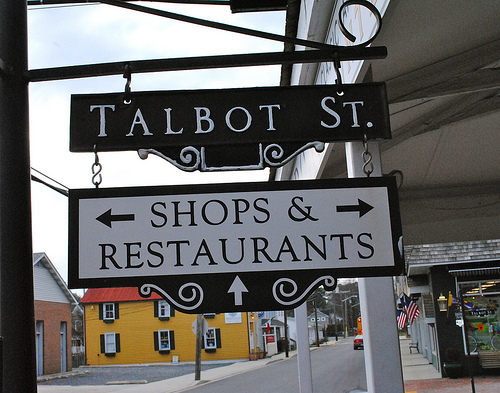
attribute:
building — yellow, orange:
[71, 285, 257, 377]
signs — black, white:
[82, 102, 395, 277]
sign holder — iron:
[330, 136, 407, 387]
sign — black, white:
[71, 190, 408, 290]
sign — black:
[63, 62, 389, 170]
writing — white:
[94, 110, 364, 133]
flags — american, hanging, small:
[396, 296, 428, 334]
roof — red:
[79, 284, 150, 301]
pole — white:
[316, 79, 412, 385]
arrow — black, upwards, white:
[77, 202, 148, 230]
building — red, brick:
[22, 304, 89, 379]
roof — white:
[36, 250, 75, 301]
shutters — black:
[99, 331, 109, 356]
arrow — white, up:
[227, 273, 265, 304]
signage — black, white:
[78, 101, 353, 130]